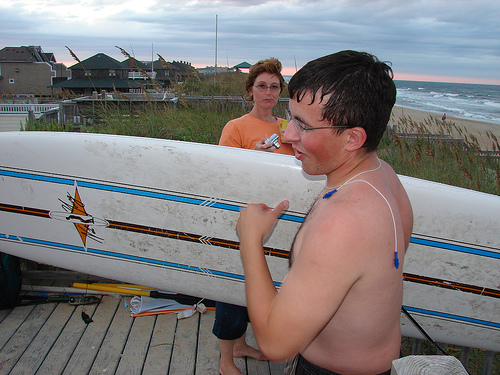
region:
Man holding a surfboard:
[0, 63, 497, 370]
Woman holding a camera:
[221, 62, 291, 148]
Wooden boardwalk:
[0, 295, 290, 373]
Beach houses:
[0, 41, 202, 96]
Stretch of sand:
[390, 99, 497, 144]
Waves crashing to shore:
[388, 87, 499, 124]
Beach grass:
[24, 103, 496, 190]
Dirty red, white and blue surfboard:
[0, 127, 498, 349]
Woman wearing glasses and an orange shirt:
[219, 56, 291, 166]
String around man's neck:
[322, 157, 398, 267]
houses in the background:
[3, 46, 187, 93]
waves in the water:
[403, 84, 490, 114]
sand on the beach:
[403, 108, 482, 150]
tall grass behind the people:
[400, 114, 497, 172]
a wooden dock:
[13, 300, 269, 371]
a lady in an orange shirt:
[214, 50, 290, 146]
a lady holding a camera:
[226, 55, 299, 159]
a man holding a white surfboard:
[8, 75, 498, 358]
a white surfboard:
[1, 120, 495, 359]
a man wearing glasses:
[276, 59, 386, 190]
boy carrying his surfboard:
[207, 52, 445, 351]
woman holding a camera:
[213, 69, 308, 168]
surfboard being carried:
[0, 120, 497, 343]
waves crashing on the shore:
[409, 79, 496, 111]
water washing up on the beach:
[431, 100, 499, 128]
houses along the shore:
[22, 56, 229, 107]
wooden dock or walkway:
[10, 304, 177, 374]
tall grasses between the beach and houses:
[57, 99, 213, 140]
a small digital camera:
[258, 131, 283, 151]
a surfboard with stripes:
[4, 131, 234, 296]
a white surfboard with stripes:
[0, 130, 237, 305]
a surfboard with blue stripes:
[1, 131, 237, 296]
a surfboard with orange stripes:
[1, 127, 223, 290]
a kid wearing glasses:
[286, 110, 311, 132]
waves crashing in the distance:
[418, 83, 495, 108]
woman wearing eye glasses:
[258, 84, 278, 93]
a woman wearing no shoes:
[210, 344, 260, 369]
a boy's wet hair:
[295, 47, 392, 139]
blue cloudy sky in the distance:
[344, 7, 499, 49]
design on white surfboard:
[53, 175, 114, 264]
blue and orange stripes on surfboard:
[103, 169, 214, 286]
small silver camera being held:
[250, 124, 282, 148]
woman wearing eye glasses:
[226, 51, 285, 122]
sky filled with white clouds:
[231, 0, 499, 51]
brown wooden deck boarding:
[1, 329, 206, 374]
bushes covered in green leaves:
[99, 101, 217, 135]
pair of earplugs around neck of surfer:
[320, 150, 413, 277]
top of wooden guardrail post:
[379, 347, 479, 374]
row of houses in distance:
[1, 40, 211, 108]